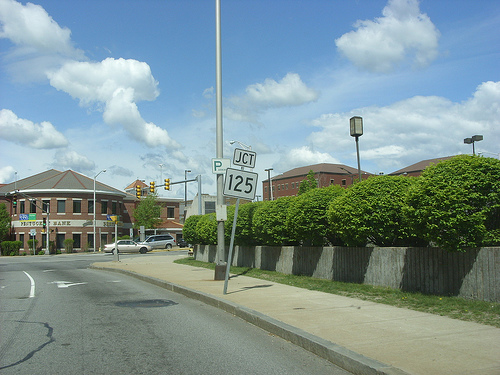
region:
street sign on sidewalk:
[227, 144, 267, 291]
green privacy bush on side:
[409, 159, 495, 250]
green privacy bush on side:
[335, 178, 412, 255]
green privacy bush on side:
[289, 187, 330, 249]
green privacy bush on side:
[263, 202, 293, 242]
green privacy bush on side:
[223, 204, 250, 239]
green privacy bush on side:
[195, 215, 220, 234]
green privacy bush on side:
[177, 220, 197, 237]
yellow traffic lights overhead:
[121, 182, 181, 196]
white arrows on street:
[46, 268, 94, 300]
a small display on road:
[221, 152, 271, 214]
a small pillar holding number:
[215, 201, 240, 298]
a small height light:
[334, 127, 369, 179]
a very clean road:
[10, 269, 322, 372]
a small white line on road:
[11, 257, 47, 304]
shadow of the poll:
[243, 266, 275, 300]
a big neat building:
[13, 155, 149, 276]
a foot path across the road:
[146, 242, 490, 367]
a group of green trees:
[180, 154, 496, 252]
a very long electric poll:
[206, 17, 244, 309]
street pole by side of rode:
[207, 108, 284, 300]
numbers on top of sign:
[210, 141, 264, 243]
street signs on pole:
[205, 147, 267, 229]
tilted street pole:
[177, 127, 279, 314]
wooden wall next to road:
[171, 251, 459, 302]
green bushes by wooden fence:
[122, 157, 484, 265]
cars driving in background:
[47, 221, 179, 283]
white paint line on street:
[15, 247, 66, 307]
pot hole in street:
[122, 282, 173, 322]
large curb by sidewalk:
[247, 304, 352, 368]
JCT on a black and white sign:
[228, 146, 261, 171]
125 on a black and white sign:
[218, 167, 257, 204]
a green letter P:
[210, 148, 230, 175]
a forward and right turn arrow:
[41, 268, 100, 308]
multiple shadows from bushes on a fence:
[246, 244, 476, 291]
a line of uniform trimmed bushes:
[248, 179, 496, 256]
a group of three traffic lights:
[130, 178, 172, 198]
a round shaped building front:
[15, 153, 133, 260]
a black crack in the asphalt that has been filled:
[4, 304, 71, 374]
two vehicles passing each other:
[94, 218, 171, 260]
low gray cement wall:
[271, 241, 483, 301]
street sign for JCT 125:
[219, 139, 274, 217]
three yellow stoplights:
[128, 171, 193, 196]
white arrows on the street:
[45, 271, 95, 299]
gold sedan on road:
[98, 235, 153, 257]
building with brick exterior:
[14, 168, 117, 263]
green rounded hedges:
[275, 151, 478, 276]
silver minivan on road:
[139, 233, 179, 253]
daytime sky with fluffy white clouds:
[24, 28, 185, 170]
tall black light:
[345, 106, 377, 186]